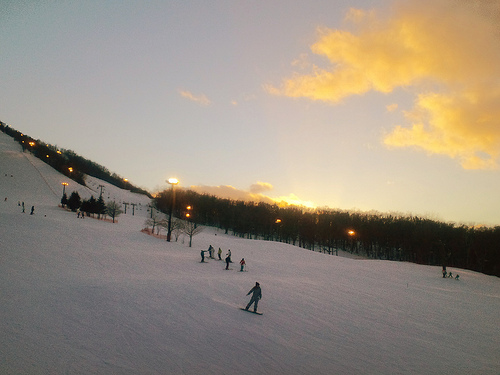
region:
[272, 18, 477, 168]
the cloud is large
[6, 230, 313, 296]
Skiers on the slopes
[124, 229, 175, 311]
Snow on the ground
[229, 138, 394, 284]
The sun Setting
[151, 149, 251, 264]
Lights on the ski slopes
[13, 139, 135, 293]
Down hill skiers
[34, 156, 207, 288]
Fence line along the ski slopes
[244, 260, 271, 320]
A snowboarder going down the hill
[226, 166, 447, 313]
Trees along the slopes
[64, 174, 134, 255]
Small trees along the ski slope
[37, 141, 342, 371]
People in the snow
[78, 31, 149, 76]
light blue sky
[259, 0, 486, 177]
white clouds in sky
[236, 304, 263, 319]
snow board on snow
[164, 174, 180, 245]
light pole on ski slope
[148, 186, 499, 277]
trees in the background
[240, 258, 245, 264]
red coat on tribe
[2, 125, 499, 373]
white ski slope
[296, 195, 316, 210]
sun behind trees and clouds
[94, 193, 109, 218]
green pine tree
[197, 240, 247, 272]
group of skiers on ski slope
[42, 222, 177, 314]
the snow is white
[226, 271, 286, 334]
the person is snowboarding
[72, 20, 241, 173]
the sky is blue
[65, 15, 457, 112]
the sky is cloudy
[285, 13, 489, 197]
the clouds are yellow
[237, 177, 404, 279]
the trees are green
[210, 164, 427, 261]
there are many trees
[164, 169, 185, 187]
the light is on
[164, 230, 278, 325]
many people are on the snow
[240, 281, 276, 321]
The snowboarder furthest down the hill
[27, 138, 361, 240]
The lights lit on the slope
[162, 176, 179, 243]
The pole nearest the group of snowboarders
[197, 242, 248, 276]
The group of snowboarders next to the nearest light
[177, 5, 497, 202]
The clouds in the sky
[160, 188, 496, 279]
The tress under the clouds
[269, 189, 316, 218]
The sun setting below the trees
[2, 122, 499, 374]
The snow covered ground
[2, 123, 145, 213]
The steep part of the hill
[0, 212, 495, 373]
The flatter portion of the hill